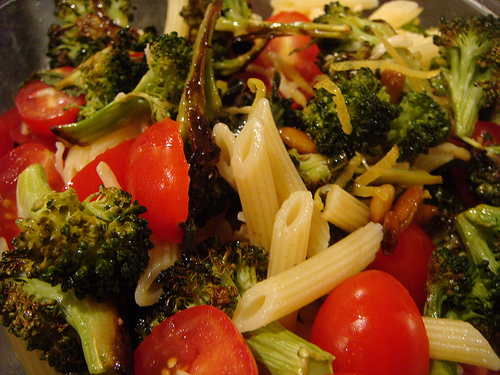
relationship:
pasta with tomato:
[225, 122, 306, 216] [133, 126, 185, 213]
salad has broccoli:
[26, 27, 443, 318] [60, 192, 136, 283]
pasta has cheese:
[225, 122, 306, 216] [349, 172, 401, 205]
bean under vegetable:
[376, 180, 437, 221] [271, 23, 371, 105]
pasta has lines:
[225, 122, 306, 216] [255, 188, 278, 210]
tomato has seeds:
[133, 126, 185, 213] [161, 356, 183, 369]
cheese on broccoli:
[349, 172, 401, 205] [60, 192, 136, 283]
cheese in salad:
[349, 172, 401, 205] [4, 50, 498, 373]